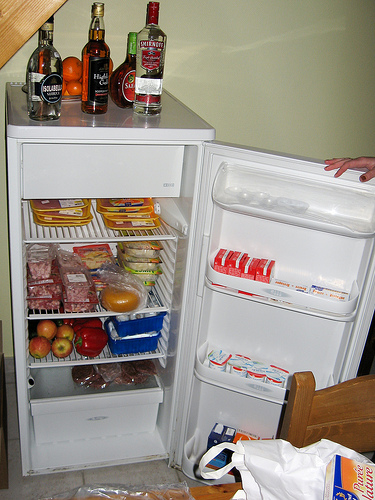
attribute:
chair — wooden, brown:
[278, 370, 374, 454]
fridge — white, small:
[6, 81, 373, 477]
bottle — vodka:
[133, 1, 167, 116]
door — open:
[168, 138, 374, 486]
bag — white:
[199, 439, 375, 500]